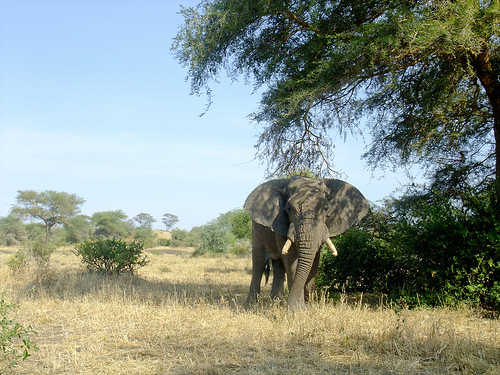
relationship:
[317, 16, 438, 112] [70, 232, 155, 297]
branches hanging from tree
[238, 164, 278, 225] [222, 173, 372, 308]
ear of elephant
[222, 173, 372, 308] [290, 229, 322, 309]
elephant has trunk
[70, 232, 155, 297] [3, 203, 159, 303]
tree in distance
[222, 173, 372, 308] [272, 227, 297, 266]
elephant has tusk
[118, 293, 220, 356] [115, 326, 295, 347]
grass on ground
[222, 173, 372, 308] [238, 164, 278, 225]
elephant has ear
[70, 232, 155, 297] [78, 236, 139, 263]
tree with leaves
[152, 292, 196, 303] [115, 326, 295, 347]
shadow on ground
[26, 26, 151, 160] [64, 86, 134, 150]
sky with no clouds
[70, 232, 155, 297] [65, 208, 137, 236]
tree on hill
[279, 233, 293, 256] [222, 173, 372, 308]
tusk on elephant